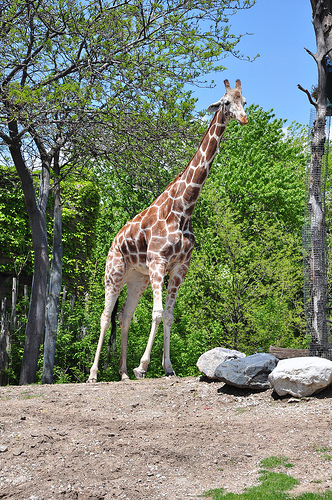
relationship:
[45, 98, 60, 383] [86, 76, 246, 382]
tree behind giraffe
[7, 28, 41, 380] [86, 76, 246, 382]
tree behind giraffe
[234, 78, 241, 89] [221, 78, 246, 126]
horn on head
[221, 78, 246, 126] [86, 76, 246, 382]
head on giraffe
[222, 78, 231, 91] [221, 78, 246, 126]
horn on head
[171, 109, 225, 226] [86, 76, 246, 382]
giraffe's neck on giraffe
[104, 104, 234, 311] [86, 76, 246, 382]
spots on giraffe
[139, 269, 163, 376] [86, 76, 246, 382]
bent leg of giraffe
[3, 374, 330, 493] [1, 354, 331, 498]
dirt on ground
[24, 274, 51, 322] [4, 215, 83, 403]
shadows of tree trunk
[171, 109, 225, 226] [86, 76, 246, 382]
giraffe's neck of giraffe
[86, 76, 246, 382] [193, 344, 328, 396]
giraffe beside rocks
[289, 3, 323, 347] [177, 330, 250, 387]
tree trunk beside rock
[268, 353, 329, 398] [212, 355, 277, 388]
rock with rock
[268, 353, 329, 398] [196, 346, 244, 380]
rock with rock